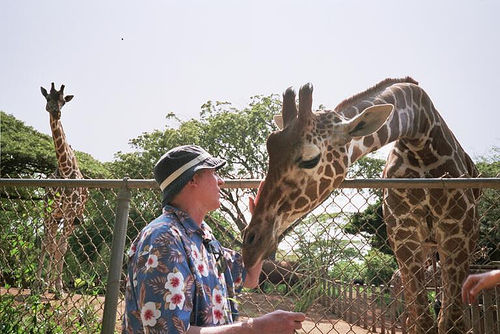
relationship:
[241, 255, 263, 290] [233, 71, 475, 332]
tongue of giraffe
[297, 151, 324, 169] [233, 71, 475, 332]
eye of giraffe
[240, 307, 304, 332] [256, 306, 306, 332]
hand of man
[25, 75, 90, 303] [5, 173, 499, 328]
giraffe behind fence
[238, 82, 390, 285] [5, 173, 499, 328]
giraffe's head in front of fence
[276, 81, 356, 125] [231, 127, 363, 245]
horns on head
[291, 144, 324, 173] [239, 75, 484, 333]
eye of giraffe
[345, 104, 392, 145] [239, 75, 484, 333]
ear of giraffe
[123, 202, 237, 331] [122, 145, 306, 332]
floral shirt on man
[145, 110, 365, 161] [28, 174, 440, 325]
trees behind fence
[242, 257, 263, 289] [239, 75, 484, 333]
tongue sticking out of giraffe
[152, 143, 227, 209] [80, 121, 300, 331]
hat on man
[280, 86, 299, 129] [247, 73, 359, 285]
horn on head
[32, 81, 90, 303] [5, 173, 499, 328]
giraffe behind fence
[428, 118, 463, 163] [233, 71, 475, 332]
spot on giraffe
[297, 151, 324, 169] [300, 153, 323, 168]
eye with eyelashes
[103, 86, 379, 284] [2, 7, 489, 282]
tree in background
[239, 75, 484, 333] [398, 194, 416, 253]
giraffe with spots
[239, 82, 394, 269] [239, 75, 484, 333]
giraffe's head of giraffe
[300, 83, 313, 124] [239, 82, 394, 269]
horn on giraffe's head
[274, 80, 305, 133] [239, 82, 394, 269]
horn on giraffe's head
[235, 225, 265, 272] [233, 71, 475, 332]
giraffe's nose on giraffe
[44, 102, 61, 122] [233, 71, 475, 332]
giraffe's nose on giraffe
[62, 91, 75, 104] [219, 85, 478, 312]
ear of giraffe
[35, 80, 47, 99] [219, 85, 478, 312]
ear of giraffe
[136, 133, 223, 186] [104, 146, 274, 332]
hat of man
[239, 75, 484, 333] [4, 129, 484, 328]
giraffe standing in enclosure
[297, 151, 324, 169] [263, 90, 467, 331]
eye of giraffe